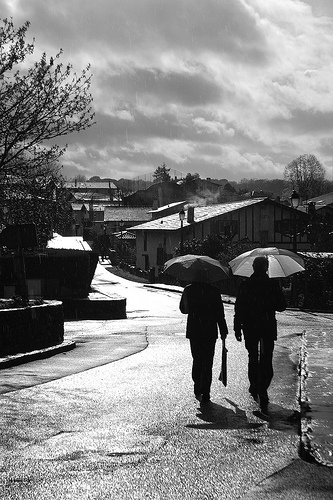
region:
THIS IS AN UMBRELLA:
[172, 252, 227, 277]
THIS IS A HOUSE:
[107, 208, 150, 223]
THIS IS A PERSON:
[175, 286, 228, 393]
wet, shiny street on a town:
[1, 258, 330, 498]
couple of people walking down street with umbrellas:
[159, 243, 307, 420]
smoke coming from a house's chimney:
[182, 189, 221, 226]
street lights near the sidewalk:
[178, 207, 186, 287]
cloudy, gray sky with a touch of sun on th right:
[0, 2, 332, 182]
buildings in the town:
[2, 175, 332, 321]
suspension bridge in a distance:
[117, 166, 187, 192]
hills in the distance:
[85, 175, 330, 198]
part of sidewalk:
[294, 324, 330, 466]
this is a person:
[178, 267, 236, 400]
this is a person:
[233, 252, 294, 419]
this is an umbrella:
[161, 252, 230, 287]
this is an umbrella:
[228, 245, 307, 280]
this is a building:
[126, 194, 271, 267]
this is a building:
[100, 198, 150, 256]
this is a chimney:
[184, 201, 199, 227]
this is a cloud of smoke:
[181, 184, 226, 204]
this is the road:
[8, 282, 332, 497]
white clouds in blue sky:
[109, 27, 141, 92]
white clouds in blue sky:
[150, 9, 202, 73]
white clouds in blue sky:
[147, 27, 191, 91]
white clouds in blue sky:
[130, 27, 199, 78]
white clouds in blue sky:
[147, 54, 181, 106]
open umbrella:
[170, 255, 217, 282]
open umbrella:
[233, 248, 317, 286]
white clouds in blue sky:
[126, 94, 147, 125]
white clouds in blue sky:
[184, 47, 216, 89]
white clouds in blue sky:
[121, 71, 140, 100]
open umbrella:
[155, 252, 236, 282]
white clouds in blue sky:
[90, 34, 111, 48]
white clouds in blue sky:
[220, 89, 291, 134]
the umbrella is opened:
[229, 245, 305, 278]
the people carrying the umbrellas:
[161, 245, 305, 406]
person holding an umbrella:
[157, 243, 238, 422]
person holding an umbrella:
[220, 239, 309, 418]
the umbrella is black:
[157, 253, 231, 290]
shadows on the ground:
[189, 397, 302, 446]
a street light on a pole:
[173, 204, 188, 256]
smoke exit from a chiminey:
[174, 176, 231, 225]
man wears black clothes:
[230, 255, 293, 411]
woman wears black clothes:
[172, 260, 231, 422]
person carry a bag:
[177, 262, 234, 413]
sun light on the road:
[74, 343, 161, 448]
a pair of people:
[160, 233, 310, 437]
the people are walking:
[165, 225, 309, 447]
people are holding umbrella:
[163, 218, 309, 443]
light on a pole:
[173, 200, 191, 254]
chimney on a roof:
[183, 197, 197, 225]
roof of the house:
[132, 198, 259, 244]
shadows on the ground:
[184, 385, 331, 463]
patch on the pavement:
[0, 324, 155, 393]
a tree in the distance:
[270, 138, 326, 213]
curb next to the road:
[3, 335, 78, 373]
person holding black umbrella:
[160, 252, 231, 406]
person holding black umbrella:
[227, 245, 304, 402]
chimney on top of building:
[186, 205, 195, 222]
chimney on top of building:
[151, 196, 159, 209]